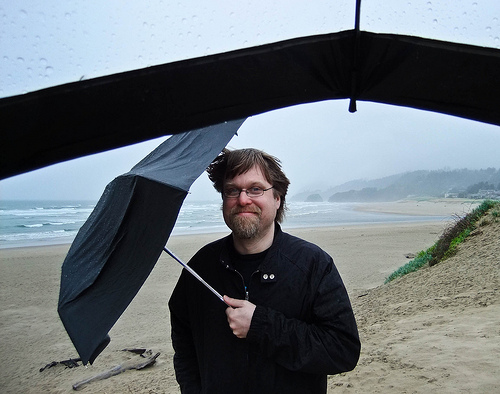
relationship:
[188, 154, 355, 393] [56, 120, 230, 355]
man with umbrella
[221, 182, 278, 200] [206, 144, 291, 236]
glasses on face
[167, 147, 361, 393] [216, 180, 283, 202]
man has glasses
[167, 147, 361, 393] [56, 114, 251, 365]
man holding umbrella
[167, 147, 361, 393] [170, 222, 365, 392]
man wearing black shirt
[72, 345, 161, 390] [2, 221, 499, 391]
wood on beach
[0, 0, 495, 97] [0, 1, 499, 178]
drops on umbrella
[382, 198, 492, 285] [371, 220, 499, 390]
plants in sand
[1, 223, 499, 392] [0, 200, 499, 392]
footprints on sand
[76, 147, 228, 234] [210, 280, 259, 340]
umbrella in hand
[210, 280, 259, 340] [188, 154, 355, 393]
hand on man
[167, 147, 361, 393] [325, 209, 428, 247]
man on beach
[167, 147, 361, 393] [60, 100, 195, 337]
man holding umbrella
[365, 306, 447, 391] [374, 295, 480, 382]
footprints in sand